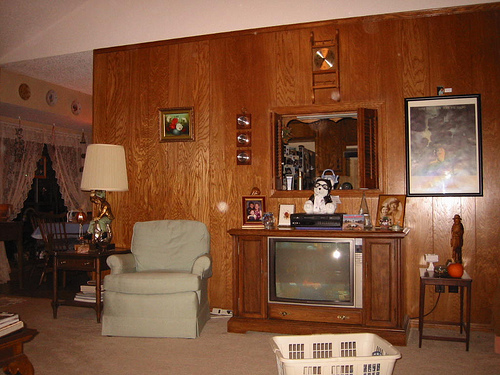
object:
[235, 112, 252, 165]
plaques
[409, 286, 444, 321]
cord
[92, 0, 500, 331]
paneling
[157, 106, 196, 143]
painting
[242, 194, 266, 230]
picture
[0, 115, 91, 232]
curtains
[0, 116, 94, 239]
window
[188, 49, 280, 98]
wooden panels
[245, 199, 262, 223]
portrait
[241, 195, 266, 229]
frame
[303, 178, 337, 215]
bear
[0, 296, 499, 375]
carpet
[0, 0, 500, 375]
livingroom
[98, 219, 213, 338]
armchair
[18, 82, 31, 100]
plate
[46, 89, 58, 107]
plate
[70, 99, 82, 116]
plate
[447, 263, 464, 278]
pumpkin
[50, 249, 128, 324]
table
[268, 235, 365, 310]
tv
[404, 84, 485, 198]
picture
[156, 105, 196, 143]
picture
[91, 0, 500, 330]
panelled wall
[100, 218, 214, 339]
train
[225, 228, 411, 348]
cabinet television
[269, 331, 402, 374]
basket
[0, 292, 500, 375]
floor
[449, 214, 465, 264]
statue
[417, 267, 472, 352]
table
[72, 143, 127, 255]
lamp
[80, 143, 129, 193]
shade